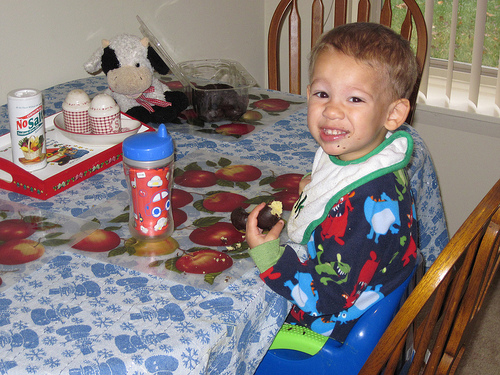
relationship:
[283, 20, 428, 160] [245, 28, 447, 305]
head on baby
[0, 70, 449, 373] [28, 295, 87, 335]
table cloth on snowman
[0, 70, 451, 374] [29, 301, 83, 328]
table cloth on snowman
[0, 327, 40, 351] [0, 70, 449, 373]
snowman on table cloth